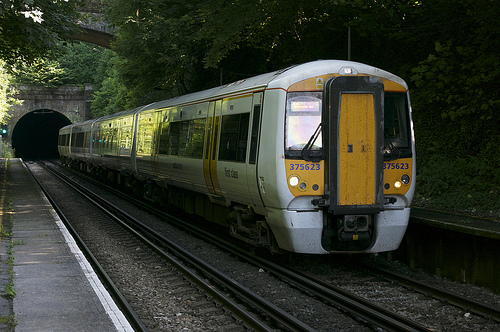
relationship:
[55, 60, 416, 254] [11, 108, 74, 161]
train coming out tunnel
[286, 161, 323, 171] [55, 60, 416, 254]
number on train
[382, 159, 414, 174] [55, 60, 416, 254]
number on train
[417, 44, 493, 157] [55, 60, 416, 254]
tree by train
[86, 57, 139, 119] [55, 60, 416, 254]
tree by train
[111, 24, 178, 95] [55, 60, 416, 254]
tree by train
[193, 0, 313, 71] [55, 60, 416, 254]
tree by train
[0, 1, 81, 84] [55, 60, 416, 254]
tree by train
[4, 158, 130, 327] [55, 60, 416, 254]
path by train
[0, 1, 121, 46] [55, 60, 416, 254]
railing above train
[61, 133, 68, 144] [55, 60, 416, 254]
window on train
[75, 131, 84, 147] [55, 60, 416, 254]
window on train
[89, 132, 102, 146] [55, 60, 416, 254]
window on train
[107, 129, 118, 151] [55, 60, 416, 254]
window on train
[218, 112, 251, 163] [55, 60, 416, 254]
window on train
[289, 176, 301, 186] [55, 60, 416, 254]
headlight of train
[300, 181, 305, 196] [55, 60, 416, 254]
light of train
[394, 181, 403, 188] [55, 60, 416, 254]
headlight of train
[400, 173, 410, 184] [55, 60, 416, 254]
light of train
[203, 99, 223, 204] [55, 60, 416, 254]
door of train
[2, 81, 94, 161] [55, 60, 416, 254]
tunnel behind train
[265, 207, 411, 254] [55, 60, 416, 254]
bumper of train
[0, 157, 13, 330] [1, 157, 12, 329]
grass coming from concrete cracks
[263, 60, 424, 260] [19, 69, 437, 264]
front of train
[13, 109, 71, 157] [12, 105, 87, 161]
entrance to tunnel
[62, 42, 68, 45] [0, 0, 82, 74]
leaf hanging from tree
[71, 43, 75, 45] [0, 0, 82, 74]
leaf hanging from tree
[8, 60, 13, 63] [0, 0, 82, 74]
leaf hanging from tree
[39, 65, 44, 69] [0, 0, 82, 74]
leaf hanging from tree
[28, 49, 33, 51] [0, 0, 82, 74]
leaf hanging from tree